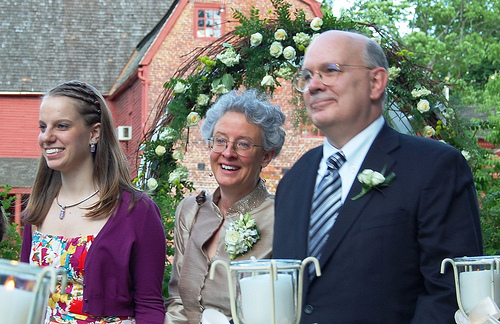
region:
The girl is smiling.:
[12, 75, 170, 321]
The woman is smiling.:
[156, 82, 297, 322]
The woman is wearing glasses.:
[152, 73, 299, 322]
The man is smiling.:
[266, 15, 488, 322]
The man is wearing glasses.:
[268, 20, 483, 322]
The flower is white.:
[177, 108, 204, 130]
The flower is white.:
[246, 24, 266, 52]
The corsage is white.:
[220, 210, 260, 261]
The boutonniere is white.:
[345, 162, 402, 207]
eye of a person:
[32, 107, 57, 138]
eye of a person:
[53, 108, 76, 133]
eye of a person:
[209, 127, 231, 157]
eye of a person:
[238, 130, 263, 161]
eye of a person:
[297, 56, 323, 96]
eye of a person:
[317, 51, 356, 92]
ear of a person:
[86, 116, 111, 143]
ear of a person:
[252, 131, 294, 178]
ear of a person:
[365, 55, 411, 113]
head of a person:
[20, 73, 125, 183]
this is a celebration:
[12, 26, 401, 283]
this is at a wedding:
[35, 36, 451, 256]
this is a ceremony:
[55, 45, 484, 247]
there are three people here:
[4, 44, 451, 254]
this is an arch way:
[158, 32, 313, 118]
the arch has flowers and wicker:
[182, 26, 311, 101]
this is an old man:
[295, 30, 465, 307]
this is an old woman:
[207, 115, 285, 225]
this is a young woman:
[22, 70, 172, 284]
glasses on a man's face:
[291, 62, 373, 90]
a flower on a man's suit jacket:
[336, 161, 394, 208]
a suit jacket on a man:
[269, 120, 480, 322]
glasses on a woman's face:
[204, 135, 260, 155]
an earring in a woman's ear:
[84, 138, 97, 156]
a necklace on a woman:
[51, 186, 103, 221]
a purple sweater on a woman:
[17, 182, 163, 322]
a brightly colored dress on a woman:
[30, 230, 128, 323]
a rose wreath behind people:
[136, 17, 498, 261]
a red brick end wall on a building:
[140, 1, 324, 205]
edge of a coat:
[196, 217, 213, 245]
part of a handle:
[263, 252, 278, 282]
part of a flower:
[338, 125, 380, 201]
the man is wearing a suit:
[273, 27, 481, 322]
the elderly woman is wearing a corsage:
[163, 89, 285, 321]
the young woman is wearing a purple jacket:
[15, 77, 165, 322]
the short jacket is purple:
[18, 178, 165, 323]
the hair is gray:
[200, 85, 287, 154]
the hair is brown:
[20, 78, 152, 225]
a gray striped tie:
[303, 149, 350, 267]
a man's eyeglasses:
[291, 65, 374, 97]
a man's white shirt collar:
[317, 113, 385, 172]